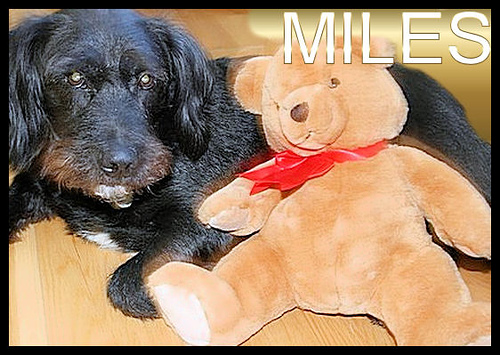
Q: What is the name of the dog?
A: Miles.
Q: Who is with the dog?
A: A teddy bear.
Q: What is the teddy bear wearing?
A: A red bow.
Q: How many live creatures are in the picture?
A: One.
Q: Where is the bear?
A: Leaning on the dog.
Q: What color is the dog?
A: Black.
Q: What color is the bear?
A: Brown.